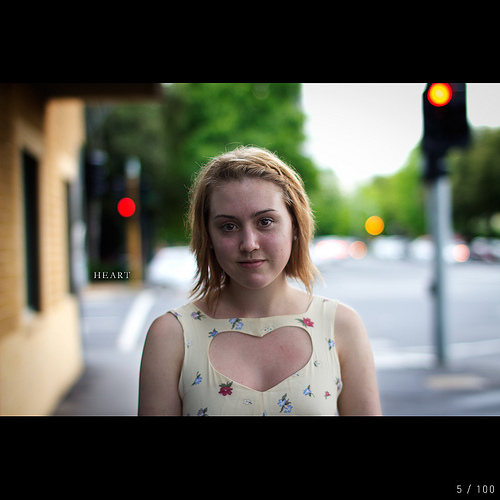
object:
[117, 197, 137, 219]
traffic light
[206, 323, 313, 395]
pattern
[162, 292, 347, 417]
woman's top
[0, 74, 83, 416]
building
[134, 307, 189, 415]
side of woman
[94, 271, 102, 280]
word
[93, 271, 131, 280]
capital letters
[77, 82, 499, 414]
background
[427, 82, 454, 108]
light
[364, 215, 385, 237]
light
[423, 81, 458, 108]
traffic light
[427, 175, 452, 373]
pole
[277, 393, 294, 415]
flower pattern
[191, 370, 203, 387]
flower pattern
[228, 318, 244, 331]
flower pattern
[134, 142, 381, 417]
woman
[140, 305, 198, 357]
woman's shoulder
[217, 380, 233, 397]
flower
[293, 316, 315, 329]
flower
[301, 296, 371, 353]
shoulder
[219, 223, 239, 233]
eyes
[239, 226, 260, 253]
nose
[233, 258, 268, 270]
mouth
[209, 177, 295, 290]
face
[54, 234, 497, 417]
street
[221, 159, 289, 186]
braid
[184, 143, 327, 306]
hair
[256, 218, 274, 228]
eyes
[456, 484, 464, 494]
number 5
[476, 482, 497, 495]
number 100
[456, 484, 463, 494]
numbers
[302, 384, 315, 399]
flower pattern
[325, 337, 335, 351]
flower pattern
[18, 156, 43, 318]
window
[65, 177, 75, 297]
window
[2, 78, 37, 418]
left side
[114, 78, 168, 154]
trees